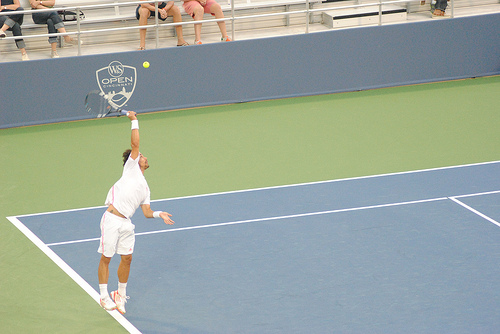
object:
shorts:
[184, 1, 233, 18]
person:
[182, 0, 229, 46]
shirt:
[101, 146, 153, 221]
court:
[1, 64, 496, 332]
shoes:
[98, 289, 129, 313]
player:
[39, 89, 227, 323]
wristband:
[130, 119, 139, 130]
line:
[271, 177, 367, 185]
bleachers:
[52, 4, 243, 46]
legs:
[36, 6, 67, 47]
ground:
[409, 107, 445, 142]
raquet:
[80, 87, 126, 117]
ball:
[142, 60, 149, 67]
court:
[300, 264, 358, 309]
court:
[251, 222, 389, 274]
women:
[0, 0, 75, 60]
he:
[94, 107, 177, 317]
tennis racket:
[77, 86, 134, 128]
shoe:
[95, 294, 117, 311]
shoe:
[113, 289, 125, 313]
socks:
[99, 283, 127, 300]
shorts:
[96, 212, 137, 258]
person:
[97, 110, 170, 312]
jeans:
[0, 5, 64, 48]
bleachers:
[5, 0, 497, 60]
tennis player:
[94, 110, 175, 319]